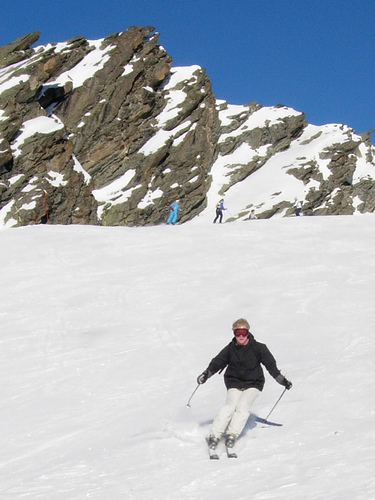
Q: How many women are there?
A: One.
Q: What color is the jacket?
A: Black.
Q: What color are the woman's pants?
A: White.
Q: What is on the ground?
A: Snow.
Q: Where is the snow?
A: On the ground.